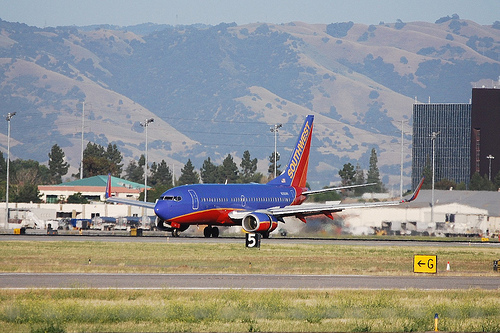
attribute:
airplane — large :
[135, 163, 326, 242]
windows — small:
[202, 195, 292, 202]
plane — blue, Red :
[146, 114, 425, 242]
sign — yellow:
[406, 252, 445, 279]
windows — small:
[236, 190, 288, 211]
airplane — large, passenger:
[110, 114, 422, 249]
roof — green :
[58, 174, 150, 188]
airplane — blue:
[109, 112, 423, 237]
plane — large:
[97, 104, 427, 256]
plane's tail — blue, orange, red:
[260, 96, 343, 198]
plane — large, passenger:
[98, 102, 390, 267]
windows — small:
[199, 193, 292, 203]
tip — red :
[408, 175, 429, 200]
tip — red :
[101, 172, 112, 199]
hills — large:
[1, 3, 499, 178]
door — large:
[186, 189, 201, 209]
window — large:
[156, 190, 182, 206]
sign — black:
[244, 229, 264, 249]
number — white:
[246, 231, 256, 246]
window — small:
[199, 197, 211, 205]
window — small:
[250, 192, 265, 202]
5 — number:
[422, 255, 439, 275]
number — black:
[242, 230, 257, 247]